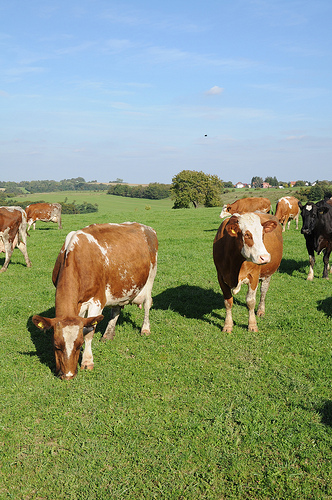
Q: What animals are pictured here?
A: Cows.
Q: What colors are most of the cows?
A: Brown and white.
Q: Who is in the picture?
A: No one.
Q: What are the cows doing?
A: Grazing.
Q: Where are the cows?
A: Field.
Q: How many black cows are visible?
A: One.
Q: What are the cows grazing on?
A: Grass.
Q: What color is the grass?
A: Green.